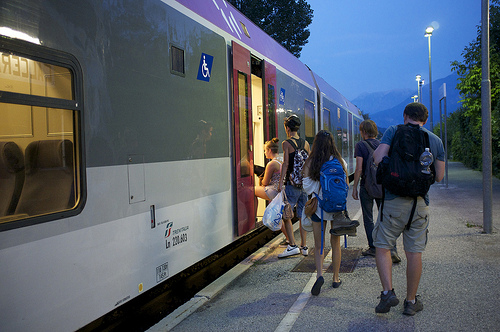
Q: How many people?
A: 5.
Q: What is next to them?
A: The train.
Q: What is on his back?
A: A backpack.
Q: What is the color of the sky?
A: Blue.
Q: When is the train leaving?
A: Now.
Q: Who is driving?
A: The conductor.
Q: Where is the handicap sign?
A: On the side of the train.